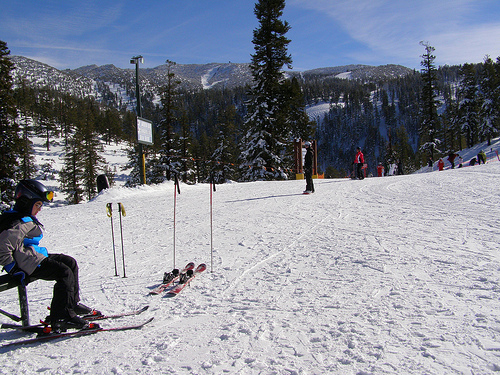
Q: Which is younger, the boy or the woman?
A: The boy is younger than the woman.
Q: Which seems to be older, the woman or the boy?
A: The woman is older than the boy.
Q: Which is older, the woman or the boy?
A: The woman is older than the boy.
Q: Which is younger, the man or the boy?
A: The boy is younger than the man.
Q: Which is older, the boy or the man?
A: The man is older than the boy.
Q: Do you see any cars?
A: No, there are no cars.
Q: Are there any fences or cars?
A: No, there are no cars or fences.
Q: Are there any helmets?
A: Yes, there is a helmet.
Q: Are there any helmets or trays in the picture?
A: Yes, there is a helmet.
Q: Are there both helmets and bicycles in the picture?
A: No, there is a helmet but no bicycles.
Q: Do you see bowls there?
A: No, there are no bowls.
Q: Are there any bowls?
A: No, there are no bowls.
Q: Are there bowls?
A: No, there are no bowls.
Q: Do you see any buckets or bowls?
A: No, there are no bowls or buckets.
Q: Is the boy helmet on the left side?
A: Yes, the helmet is on the left of the image.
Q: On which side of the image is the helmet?
A: The helmet is on the left of the image.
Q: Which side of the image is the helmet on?
A: The helmet is on the left of the image.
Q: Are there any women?
A: Yes, there is a woman.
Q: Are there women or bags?
A: Yes, there is a woman.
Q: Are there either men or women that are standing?
A: Yes, the woman is standing.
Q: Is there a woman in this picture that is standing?
A: Yes, there is a woman that is standing.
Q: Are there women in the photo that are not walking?
A: Yes, there is a woman that is standing.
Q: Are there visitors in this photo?
A: No, there are no visitors.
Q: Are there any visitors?
A: No, there are no visitors.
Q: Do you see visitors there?
A: No, there are no visitors.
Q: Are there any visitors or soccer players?
A: No, there are no visitors or soccer players.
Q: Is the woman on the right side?
A: Yes, the woman is on the right of the image.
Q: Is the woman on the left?
A: No, the woman is on the right of the image.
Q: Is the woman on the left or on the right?
A: The woman is on the right of the image.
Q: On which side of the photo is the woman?
A: The woman is on the right of the image.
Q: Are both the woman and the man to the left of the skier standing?
A: Yes, both the woman and the man are standing.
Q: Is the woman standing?
A: Yes, the woman is standing.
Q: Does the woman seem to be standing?
A: Yes, the woman is standing.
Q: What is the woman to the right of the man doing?
A: The woman is standing.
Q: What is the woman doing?
A: The woman is standing.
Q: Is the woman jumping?
A: No, the woman is standing.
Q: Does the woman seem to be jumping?
A: No, the woman is standing.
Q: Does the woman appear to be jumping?
A: No, the woman is standing.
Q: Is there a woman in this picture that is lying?
A: No, there is a woman but she is standing.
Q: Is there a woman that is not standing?
A: No, there is a woman but she is standing.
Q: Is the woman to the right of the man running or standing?
A: The woman is standing.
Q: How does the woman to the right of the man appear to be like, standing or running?
A: The woman is standing.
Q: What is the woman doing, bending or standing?
A: The woman is standing.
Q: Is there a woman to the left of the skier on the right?
A: Yes, there is a woman to the left of the skier.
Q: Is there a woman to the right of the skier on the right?
A: No, the woman is to the left of the skier.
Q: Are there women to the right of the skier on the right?
A: No, the woman is to the left of the skier.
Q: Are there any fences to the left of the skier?
A: No, there is a woman to the left of the skier.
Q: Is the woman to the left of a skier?
A: Yes, the woman is to the left of a skier.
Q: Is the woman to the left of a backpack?
A: No, the woman is to the left of a skier.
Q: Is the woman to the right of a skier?
A: No, the woman is to the left of a skier.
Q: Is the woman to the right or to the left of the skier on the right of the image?
A: The woman is to the left of the skier.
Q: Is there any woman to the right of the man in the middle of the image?
A: Yes, there is a woman to the right of the man.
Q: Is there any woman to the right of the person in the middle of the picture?
A: Yes, there is a woman to the right of the man.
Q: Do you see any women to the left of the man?
A: No, the woman is to the right of the man.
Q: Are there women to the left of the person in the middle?
A: No, the woman is to the right of the man.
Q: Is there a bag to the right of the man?
A: No, there is a woman to the right of the man.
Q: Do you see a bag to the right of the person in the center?
A: No, there is a woman to the right of the man.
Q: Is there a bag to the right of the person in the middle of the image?
A: No, there is a woman to the right of the man.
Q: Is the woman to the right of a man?
A: Yes, the woman is to the right of a man.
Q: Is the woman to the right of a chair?
A: No, the woman is to the right of a man.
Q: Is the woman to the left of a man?
A: No, the woman is to the right of a man.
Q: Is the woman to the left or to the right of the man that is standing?
A: The woman is to the right of the man.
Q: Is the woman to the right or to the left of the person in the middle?
A: The woman is to the right of the man.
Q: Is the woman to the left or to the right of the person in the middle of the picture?
A: The woman is to the right of the man.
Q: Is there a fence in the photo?
A: No, there are no fences.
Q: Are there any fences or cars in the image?
A: No, there are no fences or cars.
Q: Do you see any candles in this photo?
A: No, there are no candles.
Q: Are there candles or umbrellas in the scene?
A: No, there are no candles or umbrellas.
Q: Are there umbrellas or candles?
A: No, there are no candles or umbrellas.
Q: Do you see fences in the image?
A: No, there are no fences.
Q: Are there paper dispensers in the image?
A: No, there are no paper dispensers.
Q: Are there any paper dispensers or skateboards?
A: No, there are no paper dispensers or skateboards.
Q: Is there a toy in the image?
A: No, there are no toys.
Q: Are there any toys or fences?
A: No, there are no toys or fences.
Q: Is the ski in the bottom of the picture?
A: Yes, the ski is in the bottom of the image.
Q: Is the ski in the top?
A: No, the ski is in the bottom of the image.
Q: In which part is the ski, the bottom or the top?
A: The ski is in the bottom of the image.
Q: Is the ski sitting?
A: Yes, the ski is sitting.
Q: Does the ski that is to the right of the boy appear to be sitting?
A: Yes, the ski is sitting.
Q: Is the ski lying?
A: No, the ski is sitting.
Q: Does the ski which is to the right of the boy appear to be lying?
A: No, the ski is sitting.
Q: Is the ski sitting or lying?
A: The ski is sitting.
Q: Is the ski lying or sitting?
A: The ski is sitting.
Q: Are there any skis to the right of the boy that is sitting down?
A: Yes, there is a ski to the right of the boy.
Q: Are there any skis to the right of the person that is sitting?
A: Yes, there is a ski to the right of the boy.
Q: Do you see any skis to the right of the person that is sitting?
A: Yes, there is a ski to the right of the boy.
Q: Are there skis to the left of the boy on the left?
A: No, the ski is to the right of the boy.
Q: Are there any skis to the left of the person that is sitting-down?
A: No, the ski is to the right of the boy.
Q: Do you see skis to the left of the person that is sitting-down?
A: No, the ski is to the right of the boy.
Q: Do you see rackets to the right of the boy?
A: No, there is a ski to the right of the boy.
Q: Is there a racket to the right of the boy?
A: No, there is a ski to the right of the boy.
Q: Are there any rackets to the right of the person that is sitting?
A: No, there is a ski to the right of the boy.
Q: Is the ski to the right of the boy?
A: Yes, the ski is to the right of the boy.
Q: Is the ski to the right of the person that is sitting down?
A: Yes, the ski is to the right of the boy.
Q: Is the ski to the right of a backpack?
A: No, the ski is to the right of the boy.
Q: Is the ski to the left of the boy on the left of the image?
A: No, the ski is to the right of the boy.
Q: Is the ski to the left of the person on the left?
A: No, the ski is to the right of the boy.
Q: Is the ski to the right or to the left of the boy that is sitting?
A: The ski is to the right of the boy.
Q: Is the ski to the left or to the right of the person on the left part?
A: The ski is to the right of the boy.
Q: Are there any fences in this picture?
A: No, there are no fences.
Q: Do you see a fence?
A: No, there are no fences.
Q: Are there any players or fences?
A: No, there are no fences or players.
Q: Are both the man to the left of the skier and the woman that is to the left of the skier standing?
A: Yes, both the man and the woman are standing.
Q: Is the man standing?
A: Yes, the man is standing.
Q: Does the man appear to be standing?
A: Yes, the man is standing.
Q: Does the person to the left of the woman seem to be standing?
A: Yes, the man is standing.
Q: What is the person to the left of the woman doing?
A: The man is standing.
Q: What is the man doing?
A: The man is standing.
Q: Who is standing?
A: The man is standing.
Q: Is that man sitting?
A: No, the man is standing.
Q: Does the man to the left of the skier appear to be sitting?
A: No, the man is standing.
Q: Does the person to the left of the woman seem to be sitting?
A: No, the man is standing.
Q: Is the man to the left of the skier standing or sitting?
A: The man is standing.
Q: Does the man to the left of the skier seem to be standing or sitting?
A: The man is standing.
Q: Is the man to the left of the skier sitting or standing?
A: The man is standing.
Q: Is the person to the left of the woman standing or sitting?
A: The man is standing.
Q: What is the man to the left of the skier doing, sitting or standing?
A: The man is standing.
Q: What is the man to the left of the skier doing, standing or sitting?
A: The man is standing.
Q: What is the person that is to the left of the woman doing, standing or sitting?
A: The man is standing.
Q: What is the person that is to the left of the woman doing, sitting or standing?
A: The man is standing.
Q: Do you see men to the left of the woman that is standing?
A: Yes, there is a man to the left of the woman.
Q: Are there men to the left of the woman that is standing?
A: Yes, there is a man to the left of the woman.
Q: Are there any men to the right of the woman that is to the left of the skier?
A: No, the man is to the left of the woman.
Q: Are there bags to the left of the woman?
A: No, there is a man to the left of the woman.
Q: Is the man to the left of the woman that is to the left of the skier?
A: Yes, the man is to the left of the woman.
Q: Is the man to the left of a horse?
A: No, the man is to the left of the woman.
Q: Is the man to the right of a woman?
A: No, the man is to the left of a woman.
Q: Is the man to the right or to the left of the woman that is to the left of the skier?
A: The man is to the left of the woman.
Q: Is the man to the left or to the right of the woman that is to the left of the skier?
A: The man is to the left of the woman.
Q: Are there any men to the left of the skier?
A: Yes, there is a man to the left of the skier.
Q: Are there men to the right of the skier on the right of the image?
A: No, the man is to the left of the skier.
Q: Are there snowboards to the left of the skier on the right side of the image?
A: No, there is a man to the left of the skier.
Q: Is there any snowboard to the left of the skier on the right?
A: No, there is a man to the left of the skier.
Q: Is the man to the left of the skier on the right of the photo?
A: Yes, the man is to the left of the skier.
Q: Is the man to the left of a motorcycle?
A: No, the man is to the left of the skier.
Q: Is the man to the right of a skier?
A: No, the man is to the left of a skier.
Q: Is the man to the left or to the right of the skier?
A: The man is to the left of the skier.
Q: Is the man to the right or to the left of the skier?
A: The man is to the left of the skier.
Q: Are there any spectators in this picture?
A: No, there are no spectators.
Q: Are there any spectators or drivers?
A: No, there are no spectators or drivers.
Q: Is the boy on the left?
A: Yes, the boy is on the left of the image.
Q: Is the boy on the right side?
A: No, the boy is on the left of the image.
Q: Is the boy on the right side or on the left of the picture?
A: The boy is on the left of the image.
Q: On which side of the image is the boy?
A: The boy is on the left of the image.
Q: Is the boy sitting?
A: Yes, the boy is sitting.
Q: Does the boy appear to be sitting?
A: Yes, the boy is sitting.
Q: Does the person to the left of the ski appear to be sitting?
A: Yes, the boy is sitting.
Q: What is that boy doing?
A: The boy is sitting.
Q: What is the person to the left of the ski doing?
A: The boy is sitting.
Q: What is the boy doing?
A: The boy is sitting.